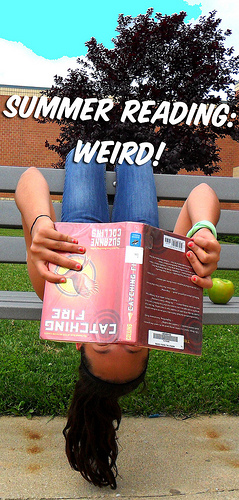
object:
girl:
[62, 132, 161, 405]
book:
[44, 218, 199, 338]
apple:
[207, 274, 234, 308]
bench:
[1, 168, 16, 318]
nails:
[71, 226, 85, 279]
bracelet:
[14, 209, 213, 258]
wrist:
[28, 208, 54, 235]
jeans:
[58, 139, 163, 224]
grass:
[12, 343, 65, 408]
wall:
[4, 105, 42, 161]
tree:
[68, 15, 236, 140]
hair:
[44, 375, 134, 484]